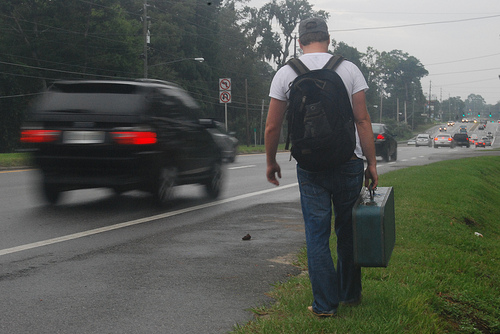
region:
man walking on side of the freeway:
[261, 16, 400, 318]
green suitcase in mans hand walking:
[348, 182, 395, 267]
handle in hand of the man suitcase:
[366, 184, 376, 198]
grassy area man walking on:
[241, 156, 499, 328]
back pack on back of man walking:
[287, 56, 359, 169]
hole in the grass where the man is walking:
[461, 213, 480, 230]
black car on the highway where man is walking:
[16, 70, 225, 207]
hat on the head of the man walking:
[296, 15, 328, 35]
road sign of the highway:
[219, 76, 230, 103]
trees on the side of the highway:
[361, 50, 428, 132]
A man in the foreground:
[254, 7, 407, 322]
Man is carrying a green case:
[331, 160, 409, 282]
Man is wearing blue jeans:
[276, 153, 382, 324]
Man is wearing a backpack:
[265, 41, 367, 181]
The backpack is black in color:
[275, 45, 374, 195]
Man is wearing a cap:
[285, 3, 334, 60]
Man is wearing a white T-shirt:
[256, 47, 386, 153]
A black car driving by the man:
[0, 54, 239, 240]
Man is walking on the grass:
[286, 193, 474, 332]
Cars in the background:
[370, 100, 499, 161]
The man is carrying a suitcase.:
[259, 11, 414, 321]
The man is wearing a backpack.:
[255, 4, 410, 324]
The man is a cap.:
[251, 12, 412, 326]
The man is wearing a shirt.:
[258, 10, 413, 325]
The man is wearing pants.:
[260, 13, 408, 319]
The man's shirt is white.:
[253, 9, 410, 323]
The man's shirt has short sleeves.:
[262, 13, 407, 319]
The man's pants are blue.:
[261, 8, 411, 320]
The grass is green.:
[240, 153, 498, 332]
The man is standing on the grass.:
[221, 7, 498, 330]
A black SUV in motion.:
[20, 77, 227, 210]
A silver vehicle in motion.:
[201, 120, 238, 162]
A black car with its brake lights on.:
[370, 122, 398, 163]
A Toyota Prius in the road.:
[415, 132, 432, 148]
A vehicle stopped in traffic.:
[434, 132, 453, 148]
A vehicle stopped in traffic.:
[473, 138, 488, 148]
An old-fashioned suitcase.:
[355, 182, 395, 266]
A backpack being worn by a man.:
[282, 55, 356, 169]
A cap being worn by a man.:
[297, 17, 330, 36]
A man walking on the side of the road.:
[263, 16, 397, 318]